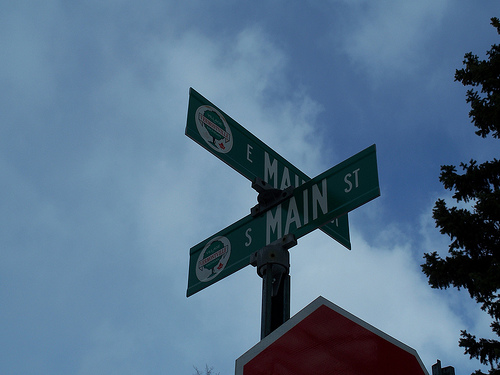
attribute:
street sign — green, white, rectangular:
[182, 85, 351, 248]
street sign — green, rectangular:
[187, 139, 383, 291]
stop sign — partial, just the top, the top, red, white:
[231, 294, 426, 374]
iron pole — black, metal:
[254, 230, 292, 339]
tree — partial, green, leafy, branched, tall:
[416, 12, 495, 374]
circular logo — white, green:
[193, 104, 234, 152]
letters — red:
[198, 111, 230, 138]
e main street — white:
[243, 138, 345, 230]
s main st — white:
[239, 160, 368, 249]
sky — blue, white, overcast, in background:
[1, 1, 499, 373]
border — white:
[234, 298, 420, 374]